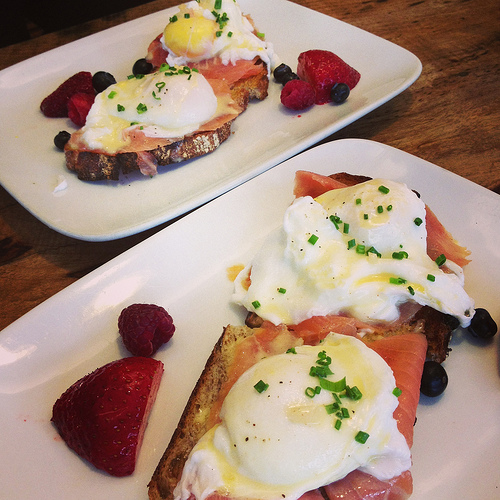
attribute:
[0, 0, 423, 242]
plate — white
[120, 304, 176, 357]
raspberry — red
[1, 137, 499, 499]
plate — white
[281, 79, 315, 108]
raspberry — red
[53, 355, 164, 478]
strawberry — red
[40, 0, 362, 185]
food — delicious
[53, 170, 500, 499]
food — delicious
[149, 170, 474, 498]
sandwich — open-faced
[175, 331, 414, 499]
egg — poached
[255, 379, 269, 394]
chive — green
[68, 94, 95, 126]
raspberry — red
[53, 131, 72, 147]
blueberry — blue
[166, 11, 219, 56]
yolk — yellow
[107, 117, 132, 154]
yolk — yellow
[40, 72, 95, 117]
strawberry — red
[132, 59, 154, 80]
blueberry — blue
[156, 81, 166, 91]
chive — green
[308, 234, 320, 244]
chive — green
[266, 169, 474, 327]
salmon — pink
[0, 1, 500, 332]
table — wood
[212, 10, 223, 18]
chive — green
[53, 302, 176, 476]
fruit — red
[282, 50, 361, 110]
fruit — red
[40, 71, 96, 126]
fruit — red